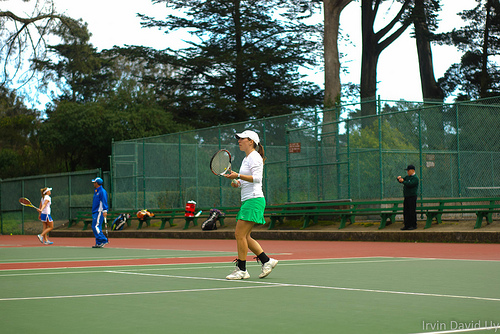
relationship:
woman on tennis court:
[209, 128, 279, 279] [0, 236, 499, 330]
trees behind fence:
[143, 1, 367, 112] [103, 101, 497, 225]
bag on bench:
[201, 210, 221, 231] [73, 192, 493, 232]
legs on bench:
[77, 212, 493, 227] [70, 192, 498, 218]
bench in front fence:
[67, 197, 500, 231] [5, 95, 498, 223]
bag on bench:
[184, 200, 198, 218] [54, 193, 498, 227]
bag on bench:
[135, 209, 156, 221] [54, 193, 498, 227]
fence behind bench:
[103, 101, 497, 225] [29, 191, 486, 257]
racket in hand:
[210, 149, 242, 189] [217, 166, 238, 181]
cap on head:
[233, 127, 263, 140] [233, 121, 263, 158]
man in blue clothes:
[89, 174, 115, 252] [90, 186, 108, 213]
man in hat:
[89, 174, 115, 252] [89, 171, 104, 183]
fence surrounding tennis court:
[3, 98, 496, 213] [0, 235, 500, 334]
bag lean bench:
[197, 206, 229, 230] [56, 197, 499, 234]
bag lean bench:
[178, 192, 207, 226] [56, 197, 499, 234]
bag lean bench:
[133, 203, 158, 225] [56, 197, 499, 234]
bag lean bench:
[107, 205, 137, 233] [56, 197, 499, 234]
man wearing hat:
[396, 164, 419, 230] [404, 163, 416, 173]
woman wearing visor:
[35, 185, 57, 244] [41, 184, 53, 198]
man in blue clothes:
[90, 177, 109, 247] [90, 186, 108, 213]